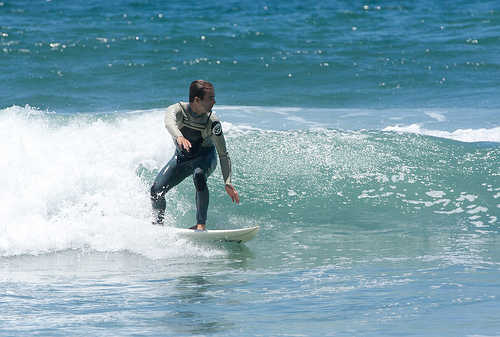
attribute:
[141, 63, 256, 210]
man — younger, healthy, looking, watching, focused, surfing, wet, standing, riding, close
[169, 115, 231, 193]
suit — close, blue, black, gray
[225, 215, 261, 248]
board — white, short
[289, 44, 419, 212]
water — calm, crashing, blue, clear, clean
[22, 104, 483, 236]
wave — small